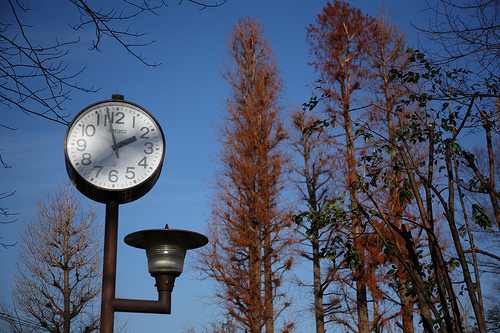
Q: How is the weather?
A: It is clear.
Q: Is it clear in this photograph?
A: Yes, it is clear.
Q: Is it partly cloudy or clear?
A: It is clear.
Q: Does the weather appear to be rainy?
A: No, it is clear.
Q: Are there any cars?
A: No, there are no cars.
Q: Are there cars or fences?
A: No, there are no cars or fences.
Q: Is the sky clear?
A: Yes, the sky is clear.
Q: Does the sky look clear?
A: Yes, the sky is clear.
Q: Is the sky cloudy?
A: No, the sky is clear.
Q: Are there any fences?
A: No, there are no fences.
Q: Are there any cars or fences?
A: No, there are no fences or cars.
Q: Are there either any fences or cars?
A: No, there are no fences or cars.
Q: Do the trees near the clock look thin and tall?
A: Yes, the trees are thin and tall.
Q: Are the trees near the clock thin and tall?
A: Yes, the trees are thin and tall.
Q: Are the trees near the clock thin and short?
A: No, the trees are thin but tall.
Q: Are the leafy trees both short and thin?
A: No, the trees are thin but tall.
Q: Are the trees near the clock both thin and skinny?
A: Yes, the trees are thin and skinny.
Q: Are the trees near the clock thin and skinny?
A: Yes, the trees are thin and skinny.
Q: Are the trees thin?
A: Yes, the trees are thin.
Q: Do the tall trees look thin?
A: Yes, the trees are thin.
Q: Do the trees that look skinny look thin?
A: Yes, the trees are thin.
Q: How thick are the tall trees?
A: The trees are thin.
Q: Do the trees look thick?
A: No, the trees are thin.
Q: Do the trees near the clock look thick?
A: No, the trees are thin.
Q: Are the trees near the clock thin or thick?
A: The trees are thin.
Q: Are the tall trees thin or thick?
A: The trees are thin.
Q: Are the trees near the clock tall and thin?
A: Yes, the trees are tall and thin.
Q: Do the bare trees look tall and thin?
A: Yes, the trees are tall and thin.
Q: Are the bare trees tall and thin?
A: Yes, the trees are tall and thin.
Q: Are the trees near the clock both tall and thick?
A: No, the trees are tall but thin.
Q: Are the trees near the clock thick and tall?
A: No, the trees are tall but thin.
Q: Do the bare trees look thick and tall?
A: No, the trees are tall but thin.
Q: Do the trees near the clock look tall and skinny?
A: Yes, the trees are tall and skinny.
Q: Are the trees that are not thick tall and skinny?
A: Yes, the trees are tall and skinny.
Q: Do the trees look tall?
A: Yes, the trees are tall.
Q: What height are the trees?
A: The trees are tall.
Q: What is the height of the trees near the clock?
A: The trees are tall.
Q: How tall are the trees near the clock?
A: The trees are tall.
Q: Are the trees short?
A: No, the trees are tall.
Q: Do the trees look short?
A: No, the trees are tall.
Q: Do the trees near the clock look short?
A: No, the trees are tall.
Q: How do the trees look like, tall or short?
A: The trees are tall.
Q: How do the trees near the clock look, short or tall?
A: The trees are tall.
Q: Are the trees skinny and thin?
A: Yes, the trees are skinny and thin.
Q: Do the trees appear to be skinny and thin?
A: Yes, the trees are skinny and thin.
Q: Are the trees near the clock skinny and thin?
A: Yes, the trees are skinny and thin.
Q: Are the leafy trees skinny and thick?
A: No, the trees are skinny but thin.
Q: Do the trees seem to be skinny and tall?
A: Yes, the trees are skinny and tall.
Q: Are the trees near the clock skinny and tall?
A: Yes, the trees are skinny and tall.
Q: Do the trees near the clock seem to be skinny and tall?
A: Yes, the trees are skinny and tall.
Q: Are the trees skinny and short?
A: No, the trees are skinny but tall.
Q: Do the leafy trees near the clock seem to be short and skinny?
A: No, the trees are skinny but tall.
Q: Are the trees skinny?
A: Yes, the trees are skinny.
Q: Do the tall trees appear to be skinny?
A: Yes, the trees are skinny.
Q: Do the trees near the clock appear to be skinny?
A: Yes, the trees are skinny.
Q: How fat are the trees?
A: The trees are skinny.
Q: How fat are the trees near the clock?
A: The trees are skinny.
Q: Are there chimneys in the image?
A: No, there are no chimneys.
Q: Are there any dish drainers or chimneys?
A: No, there are no chimneys or dish drainers.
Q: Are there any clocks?
A: Yes, there is a clock.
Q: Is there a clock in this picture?
A: Yes, there is a clock.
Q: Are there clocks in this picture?
A: Yes, there is a clock.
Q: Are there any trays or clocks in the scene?
A: Yes, there is a clock.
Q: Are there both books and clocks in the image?
A: No, there is a clock but no books.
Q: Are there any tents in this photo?
A: No, there are no tents.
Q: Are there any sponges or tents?
A: No, there are no tents or sponges.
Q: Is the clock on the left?
A: Yes, the clock is on the left of the image.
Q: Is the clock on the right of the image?
A: No, the clock is on the left of the image.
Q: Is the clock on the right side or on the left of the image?
A: The clock is on the left of the image.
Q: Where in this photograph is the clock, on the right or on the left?
A: The clock is on the left of the image.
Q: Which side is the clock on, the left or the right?
A: The clock is on the left of the image.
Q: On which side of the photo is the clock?
A: The clock is on the left of the image.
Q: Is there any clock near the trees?
A: Yes, there is a clock near the trees.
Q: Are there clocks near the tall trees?
A: Yes, there is a clock near the trees.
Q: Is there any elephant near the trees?
A: No, there is a clock near the trees.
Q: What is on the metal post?
A: The clock is on the post.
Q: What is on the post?
A: The clock is on the post.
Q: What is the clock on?
A: The clock is on the post.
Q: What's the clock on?
A: The clock is on the post.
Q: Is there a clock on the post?
A: Yes, there is a clock on the post.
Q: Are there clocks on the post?
A: Yes, there is a clock on the post.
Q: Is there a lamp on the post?
A: No, there is a clock on the post.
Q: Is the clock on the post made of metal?
A: Yes, the clock is on the post.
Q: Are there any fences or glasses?
A: No, there are no fences or glasses.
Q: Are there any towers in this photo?
A: No, there are no towers.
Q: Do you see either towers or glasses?
A: No, there are no towers or glasses.